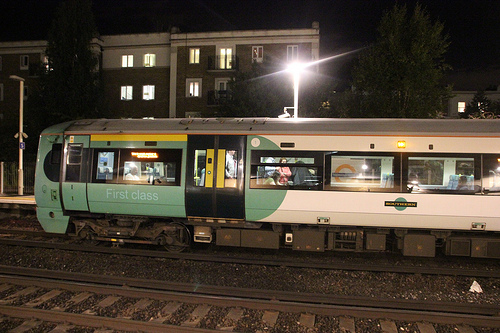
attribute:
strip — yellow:
[74, 123, 202, 163]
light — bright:
[252, 52, 346, 114]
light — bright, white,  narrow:
[278, 59, 320, 124]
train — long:
[29, 96, 499, 280]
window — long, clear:
[402, 155, 499, 195]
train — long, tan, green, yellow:
[49, 99, 497, 245]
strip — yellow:
[203, 147, 225, 187]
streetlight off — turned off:
[8, 71, 26, 196]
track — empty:
[4, 232, 492, 332]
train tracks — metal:
[3, 242, 498, 329]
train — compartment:
[23, 102, 490, 252]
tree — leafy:
[26, 19, 121, 131]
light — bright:
[267, 53, 311, 88]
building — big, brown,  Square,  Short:
[39, 23, 378, 137]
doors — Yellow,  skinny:
[188, 131, 248, 223]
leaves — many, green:
[395, 12, 445, 62]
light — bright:
[251, 44, 351, 120]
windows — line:
[65, 143, 484, 191]